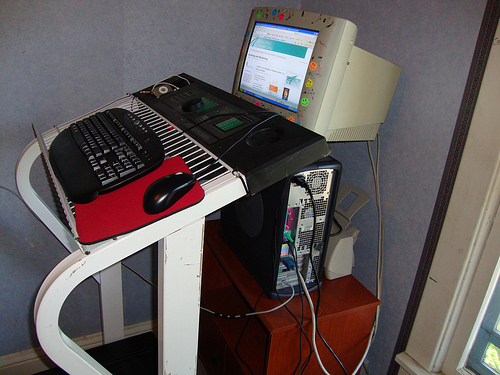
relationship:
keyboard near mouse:
[53, 105, 156, 202] [141, 167, 197, 220]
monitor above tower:
[236, 0, 404, 144] [207, 147, 336, 294]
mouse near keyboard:
[141, 167, 197, 220] [53, 105, 156, 202]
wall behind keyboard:
[1, 4, 480, 374] [53, 105, 156, 202]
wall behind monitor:
[1, 4, 480, 374] [236, 0, 404, 144]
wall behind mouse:
[1, 4, 480, 374] [141, 167, 197, 220]